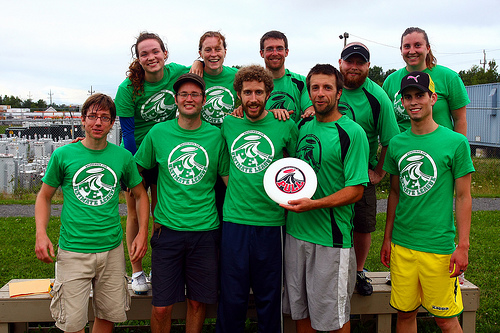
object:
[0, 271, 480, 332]
bench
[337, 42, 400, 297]
visor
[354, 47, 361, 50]
swoosh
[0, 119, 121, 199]
chain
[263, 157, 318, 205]
frisbee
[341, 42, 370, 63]
baseball cap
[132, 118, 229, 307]
uniform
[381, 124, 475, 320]
uniform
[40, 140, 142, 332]
uniform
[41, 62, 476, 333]
uniform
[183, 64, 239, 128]
uniform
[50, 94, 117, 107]
power lines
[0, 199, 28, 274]
ground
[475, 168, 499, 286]
ground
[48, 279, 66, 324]
pocket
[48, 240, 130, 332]
shorts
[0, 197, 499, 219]
trail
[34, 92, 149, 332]
man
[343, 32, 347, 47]
pole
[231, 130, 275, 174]
frisbee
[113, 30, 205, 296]
girl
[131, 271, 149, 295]
shoe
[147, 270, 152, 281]
shoe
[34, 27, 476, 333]
frisbee team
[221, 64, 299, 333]
man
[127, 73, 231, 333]
man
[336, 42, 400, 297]
man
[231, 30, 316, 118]
man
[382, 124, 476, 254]
green shirt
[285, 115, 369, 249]
green shirt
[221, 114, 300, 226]
green shirt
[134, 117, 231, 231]
green shirt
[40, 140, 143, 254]
green shirt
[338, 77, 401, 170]
green shirt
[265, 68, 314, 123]
green shirt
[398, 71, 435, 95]
cap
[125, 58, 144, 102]
ponytail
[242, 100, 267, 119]
beard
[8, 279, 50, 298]
paper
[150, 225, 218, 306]
blueshorts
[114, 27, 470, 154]
back row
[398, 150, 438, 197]
symbol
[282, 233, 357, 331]
gray shorts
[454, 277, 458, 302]
bolt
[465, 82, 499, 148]
shipping container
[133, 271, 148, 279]
white flap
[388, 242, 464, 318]
shorts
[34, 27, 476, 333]
people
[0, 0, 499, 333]
picture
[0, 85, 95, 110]
distant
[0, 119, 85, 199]
fencing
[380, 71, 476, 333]
guy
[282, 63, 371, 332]
guy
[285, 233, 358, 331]
shorts